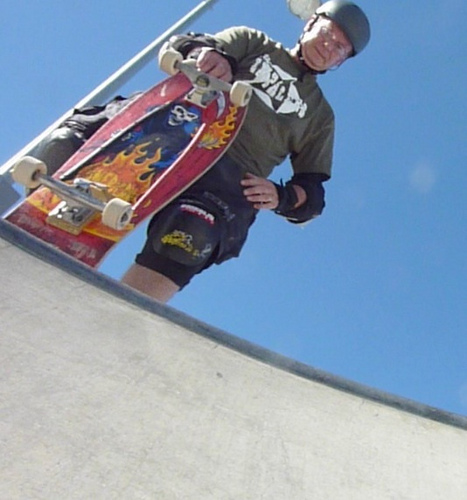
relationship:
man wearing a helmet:
[111, 3, 372, 309] [313, 0, 375, 65]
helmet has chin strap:
[313, 0, 375, 65] [294, 41, 326, 74]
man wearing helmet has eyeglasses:
[111, 3, 372, 309] [312, 22, 348, 56]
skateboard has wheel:
[6, 39, 257, 272] [229, 80, 256, 112]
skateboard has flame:
[6, 39, 257, 272] [74, 139, 165, 205]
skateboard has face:
[6, 39, 257, 272] [164, 102, 201, 134]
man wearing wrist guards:
[111, 3, 372, 309] [269, 177, 301, 222]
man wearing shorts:
[111, 3, 372, 309] [141, 158, 263, 266]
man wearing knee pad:
[111, 3, 372, 309] [148, 198, 226, 277]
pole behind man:
[8, 7, 210, 174] [111, 3, 372, 309]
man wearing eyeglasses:
[111, 3, 372, 309] [312, 22, 348, 56]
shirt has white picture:
[207, 19, 338, 200] [246, 58, 310, 122]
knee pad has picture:
[148, 198, 226, 277] [164, 229, 193, 252]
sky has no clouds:
[5, 6, 465, 316] [290, 6, 319, 20]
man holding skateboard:
[111, 3, 372, 309] [6, 39, 257, 272]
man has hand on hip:
[111, 3, 372, 309] [239, 167, 273, 227]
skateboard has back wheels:
[6, 39, 257, 272] [9, 149, 136, 239]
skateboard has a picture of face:
[6, 39, 257, 272] [164, 102, 201, 134]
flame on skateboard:
[74, 139, 165, 205] [6, 39, 257, 272]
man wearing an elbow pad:
[111, 3, 372, 309] [290, 175, 327, 229]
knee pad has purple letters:
[148, 198, 226, 277] [173, 210, 205, 220]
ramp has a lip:
[0, 229, 463, 498] [211, 329, 464, 441]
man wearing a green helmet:
[111, 3, 372, 309] [313, 0, 375, 65]